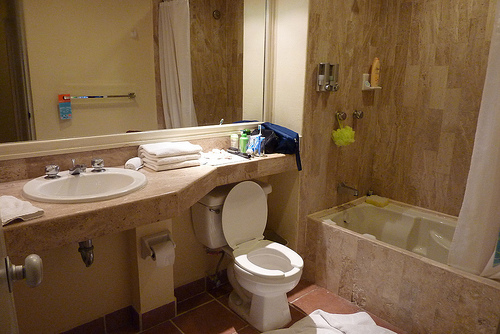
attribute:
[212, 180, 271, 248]
seat — up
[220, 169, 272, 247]
lid — up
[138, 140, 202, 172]
towels — white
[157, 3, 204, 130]
shower curtain — white, pushed to side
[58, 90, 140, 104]
rack — TOWEL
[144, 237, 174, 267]
toilet paper — rolled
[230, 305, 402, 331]
towel — white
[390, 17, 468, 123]
wall — white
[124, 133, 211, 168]
towels — folded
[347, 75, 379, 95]
shelf — small